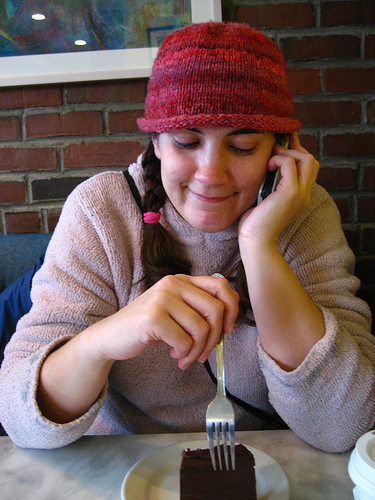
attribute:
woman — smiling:
[1, 22, 374, 453]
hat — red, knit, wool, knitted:
[135, 19, 301, 133]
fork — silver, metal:
[202, 330, 238, 473]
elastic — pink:
[142, 206, 165, 225]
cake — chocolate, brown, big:
[176, 441, 259, 500]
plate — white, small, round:
[119, 436, 293, 500]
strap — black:
[118, 165, 287, 428]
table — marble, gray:
[0, 422, 374, 499]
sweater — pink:
[2, 150, 373, 452]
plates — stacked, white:
[342, 427, 373, 500]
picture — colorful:
[1, 0, 225, 92]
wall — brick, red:
[1, 1, 374, 340]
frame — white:
[3, 0, 223, 86]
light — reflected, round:
[27, 12, 48, 26]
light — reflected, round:
[73, 38, 89, 50]